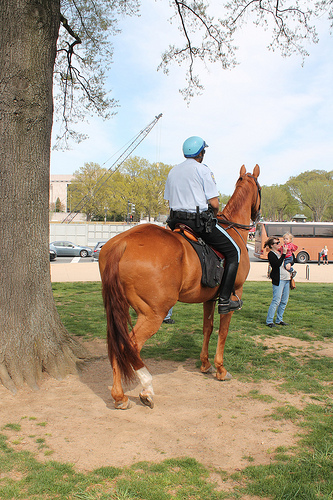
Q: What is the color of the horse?
A: Brown.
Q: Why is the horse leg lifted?
A: To make a step.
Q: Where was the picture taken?
A: At a park.